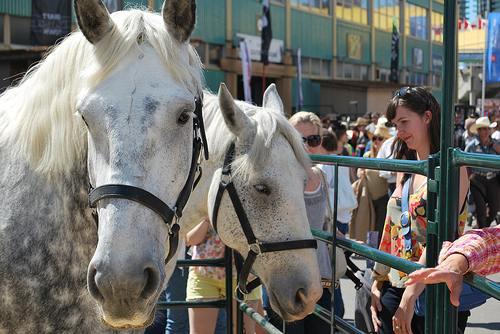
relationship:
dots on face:
[101, 89, 157, 186] [76, 29, 197, 326]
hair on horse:
[0, 10, 200, 197] [4, 4, 201, 333]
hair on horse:
[203, 87, 321, 181] [180, 82, 327, 325]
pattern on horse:
[0, 112, 100, 329] [4, 4, 201, 333]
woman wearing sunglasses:
[264, 112, 343, 333] [296, 133, 322, 148]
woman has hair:
[362, 80, 468, 333] [385, 85, 443, 162]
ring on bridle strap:
[167, 213, 182, 236] [84, 74, 210, 264]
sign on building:
[343, 35, 364, 60] [4, 0, 497, 112]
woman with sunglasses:
[362, 80, 468, 333] [394, 85, 432, 108]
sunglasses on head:
[394, 85, 432, 108] [383, 86, 444, 153]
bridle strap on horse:
[84, 74, 210, 264] [4, 4, 201, 333]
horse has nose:
[4, 4, 201, 333] [82, 223, 167, 330]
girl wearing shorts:
[187, 215, 261, 333] [184, 267, 263, 305]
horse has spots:
[4, 4, 201, 333] [0, 112, 100, 329]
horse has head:
[4, 4, 201, 333] [75, 27, 203, 325]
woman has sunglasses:
[362, 80, 468, 333] [394, 85, 432, 108]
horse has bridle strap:
[4, 4, 201, 333] [84, 74, 210, 264]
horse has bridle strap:
[180, 82, 327, 325] [208, 143, 317, 301]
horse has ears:
[4, 4, 201, 333] [67, 4, 204, 45]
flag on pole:
[256, 1, 274, 68] [257, 6, 274, 111]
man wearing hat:
[466, 115, 499, 228] [464, 112, 497, 138]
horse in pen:
[4, 4, 201, 333] [0, 106, 499, 330]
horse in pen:
[180, 82, 327, 325] [0, 106, 499, 330]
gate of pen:
[237, 139, 437, 331] [0, 106, 499, 330]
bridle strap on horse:
[208, 143, 317, 301] [180, 82, 327, 325]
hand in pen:
[405, 247, 468, 306] [0, 106, 499, 330]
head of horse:
[75, 27, 203, 325] [4, 4, 201, 333]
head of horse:
[208, 143, 317, 301] [180, 82, 327, 325]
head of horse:
[208, 143, 317, 301] [4, 4, 201, 333]